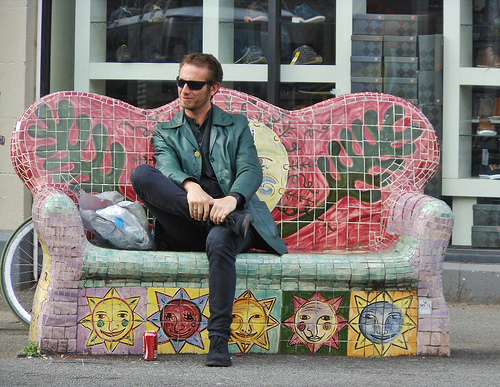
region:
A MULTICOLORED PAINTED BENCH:
[6, 66, 456, 364]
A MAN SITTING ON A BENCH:
[13, 44, 494, 370]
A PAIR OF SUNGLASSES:
[168, 65, 219, 98]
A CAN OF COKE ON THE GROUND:
[125, 326, 172, 364]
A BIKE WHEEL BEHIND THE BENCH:
[6, 211, 46, 335]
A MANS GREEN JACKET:
[146, 99, 307, 256]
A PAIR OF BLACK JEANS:
[124, 157, 244, 342]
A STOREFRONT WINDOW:
[68, 3, 360, 119]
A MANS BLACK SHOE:
[199, 330, 239, 370]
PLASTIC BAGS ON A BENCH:
[62, 183, 159, 257]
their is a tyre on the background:
[5, 226, 37, 288]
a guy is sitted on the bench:
[109, 151, 399, 376]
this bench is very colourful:
[39, 116, 136, 351]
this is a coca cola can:
[132, 315, 172, 379]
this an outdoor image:
[28, 101, 438, 376]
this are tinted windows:
[120, 31, 284, 54]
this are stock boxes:
[355, 21, 445, 152]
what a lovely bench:
[27, 97, 447, 379]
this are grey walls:
[335, 23, 462, 142]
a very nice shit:
[69, 88, 379, 378]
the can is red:
[135, 326, 174, 358]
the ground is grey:
[132, 363, 307, 383]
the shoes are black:
[206, 339, 244, 366]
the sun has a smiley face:
[77, 284, 143, 344]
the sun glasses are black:
[168, 75, 212, 95]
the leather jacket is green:
[153, 118, 292, 254]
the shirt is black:
[191, 119, 215, 184]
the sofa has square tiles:
[31, 100, 456, 359]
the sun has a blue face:
[358, 299, 419, 349]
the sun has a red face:
[150, 291, 203, 342]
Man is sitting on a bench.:
[128, 48, 294, 378]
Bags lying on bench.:
[71, 177, 153, 259]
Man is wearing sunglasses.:
[165, 69, 212, 95]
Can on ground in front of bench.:
[137, 327, 164, 368]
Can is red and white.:
[136, 325, 166, 372]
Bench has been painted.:
[9, 81, 457, 362]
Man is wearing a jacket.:
[151, 107, 287, 261]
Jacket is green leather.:
[150, 100, 290, 260]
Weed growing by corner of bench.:
[3, 335, 51, 363]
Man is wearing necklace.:
[161, 106, 218, 164]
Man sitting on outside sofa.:
[132, 50, 293, 367]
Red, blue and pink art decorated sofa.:
[8, 84, 462, 369]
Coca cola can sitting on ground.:
[134, 328, 165, 366]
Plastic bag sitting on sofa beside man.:
[80, 183, 157, 259]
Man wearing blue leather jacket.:
[147, 104, 297, 259]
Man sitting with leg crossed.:
[125, 162, 252, 263]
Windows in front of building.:
[94, 0, 349, 72]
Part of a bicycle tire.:
[2, 211, 40, 336]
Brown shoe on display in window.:
[472, 106, 498, 147]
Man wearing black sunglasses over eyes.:
[173, 73, 213, 91]